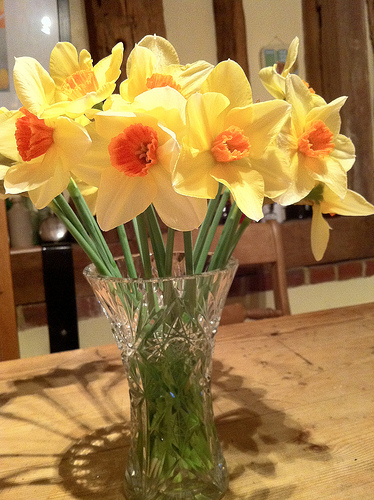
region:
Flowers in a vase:
[3, 33, 357, 315]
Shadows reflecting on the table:
[9, 360, 325, 498]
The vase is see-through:
[68, 244, 268, 497]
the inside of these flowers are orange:
[7, 65, 346, 192]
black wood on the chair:
[20, 234, 95, 363]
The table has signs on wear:
[6, 329, 369, 471]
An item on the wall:
[249, 27, 308, 89]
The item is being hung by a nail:
[249, 17, 298, 65]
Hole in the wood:
[102, 26, 137, 60]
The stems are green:
[26, 146, 265, 306]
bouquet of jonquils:
[2, 38, 372, 231]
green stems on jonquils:
[27, 200, 257, 275]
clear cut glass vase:
[82, 242, 241, 498]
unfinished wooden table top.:
[259, 300, 372, 497]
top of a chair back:
[133, 219, 301, 321]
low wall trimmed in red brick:
[236, 254, 372, 318]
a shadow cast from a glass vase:
[5, 344, 131, 497]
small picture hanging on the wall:
[256, 24, 300, 82]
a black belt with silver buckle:
[23, 213, 79, 357]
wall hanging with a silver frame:
[0, 0, 76, 111]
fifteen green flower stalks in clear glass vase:
[44, 205, 265, 301]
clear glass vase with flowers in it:
[64, 250, 247, 479]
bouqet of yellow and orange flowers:
[9, 29, 313, 222]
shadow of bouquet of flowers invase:
[19, 341, 328, 486]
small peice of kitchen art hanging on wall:
[249, 20, 307, 85]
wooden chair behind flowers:
[137, 218, 315, 339]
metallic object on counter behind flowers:
[20, 209, 77, 254]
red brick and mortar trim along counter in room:
[287, 248, 363, 296]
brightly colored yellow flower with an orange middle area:
[73, 94, 203, 217]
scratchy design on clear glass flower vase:
[65, 249, 242, 393]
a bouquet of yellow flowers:
[1, 68, 352, 237]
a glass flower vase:
[104, 237, 264, 461]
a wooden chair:
[231, 228, 287, 345]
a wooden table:
[70, 309, 329, 498]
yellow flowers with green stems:
[159, 108, 327, 325]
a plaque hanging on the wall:
[260, 28, 297, 88]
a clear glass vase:
[104, 223, 274, 498]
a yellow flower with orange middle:
[98, 92, 191, 194]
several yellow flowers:
[23, 46, 335, 290]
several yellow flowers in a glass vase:
[48, 37, 319, 493]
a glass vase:
[125, 286, 220, 484]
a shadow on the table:
[4, 368, 129, 495]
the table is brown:
[269, 330, 371, 417]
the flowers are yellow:
[196, 76, 262, 120]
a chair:
[242, 240, 293, 277]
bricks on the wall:
[296, 263, 364, 282]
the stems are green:
[103, 241, 227, 267]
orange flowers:
[114, 130, 160, 169]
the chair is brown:
[247, 235, 288, 275]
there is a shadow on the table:
[227, 368, 326, 470]